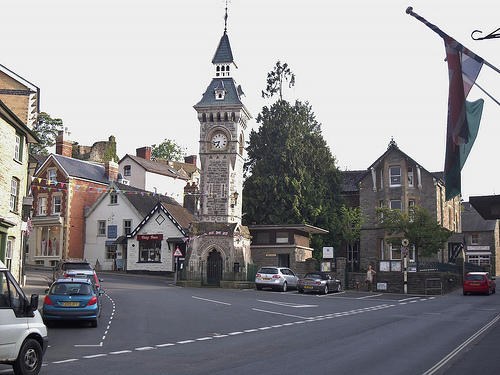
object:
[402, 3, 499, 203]
flag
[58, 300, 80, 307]
license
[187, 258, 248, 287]
iron fence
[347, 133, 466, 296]
building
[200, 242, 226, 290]
door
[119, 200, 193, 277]
shop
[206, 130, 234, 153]
clock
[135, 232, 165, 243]
red sign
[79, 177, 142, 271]
white building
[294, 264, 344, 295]
car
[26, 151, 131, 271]
building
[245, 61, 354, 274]
tree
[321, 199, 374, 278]
tree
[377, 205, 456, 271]
tree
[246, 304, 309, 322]
lines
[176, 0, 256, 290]
clock tower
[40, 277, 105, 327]
car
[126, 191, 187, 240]
triangles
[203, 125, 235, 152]
clock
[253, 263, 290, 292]
car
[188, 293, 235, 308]
lines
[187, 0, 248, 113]
steeple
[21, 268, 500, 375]
street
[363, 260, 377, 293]
woman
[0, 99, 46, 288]
building